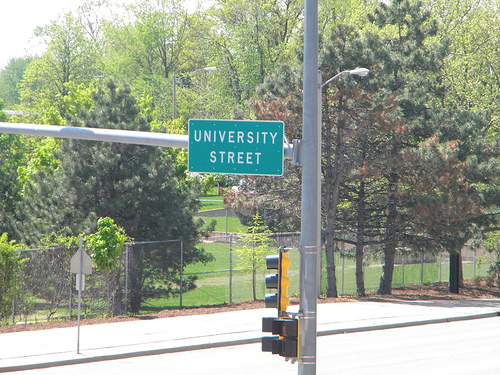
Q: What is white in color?
A: The sky.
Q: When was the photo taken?
A: On a sunny day.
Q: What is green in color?
A: Trees.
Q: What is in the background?
A: The trees.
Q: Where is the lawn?
A: Behind the fence.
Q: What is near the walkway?
A: A fence.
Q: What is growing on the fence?
A: Ivy.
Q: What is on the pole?
A: A signal light.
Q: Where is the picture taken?
A: A street.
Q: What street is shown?
A: University street.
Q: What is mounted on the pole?
A: A green street sign.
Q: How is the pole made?
A: Of metal.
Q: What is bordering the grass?
A: A fence.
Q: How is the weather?
A: Sunny and bright.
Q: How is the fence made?
A: Of metal.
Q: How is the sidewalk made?
A: Of concrete.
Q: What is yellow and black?
A: The street lights.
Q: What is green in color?
A: The trees.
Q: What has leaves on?
A: The trees.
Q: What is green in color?
A: The grass.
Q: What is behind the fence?
A: The tall evergreen tree.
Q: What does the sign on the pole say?
A: It says university street.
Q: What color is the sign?
A: The sign is green.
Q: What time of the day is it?
A: It is the day time.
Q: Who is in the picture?
A: Nobody is in the picture.